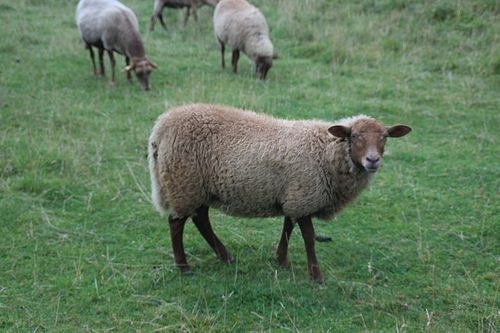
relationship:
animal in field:
[144, 101, 409, 279] [6, 4, 484, 323]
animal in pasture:
[146, 101, 413, 285] [9, 4, 484, 324]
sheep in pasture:
[75, 2, 167, 92] [9, 4, 484, 324]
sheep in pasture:
[212, 2, 282, 81] [9, 4, 484, 324]